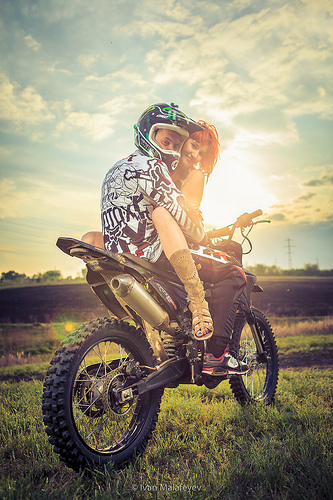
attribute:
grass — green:
[168, 413, 327, 478]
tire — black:
[36, 317, 177, 475]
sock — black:
[206, 338, 225, 357]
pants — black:
[119, 234, 258, 379]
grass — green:
[183, 395, 319, 480]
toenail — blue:
[192, 325, 203, 335]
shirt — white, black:
[102, 137, 209, 279]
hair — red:
[200, 119, 218, 177]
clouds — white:
[126, 0, 236, 80]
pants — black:
[146, 250, 233, 378]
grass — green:
[192, 406, 301, 480]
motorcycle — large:
[18, 116, 331, 461]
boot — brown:
[167, 245, 214, 340]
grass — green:
[0, 309, 331, 496]